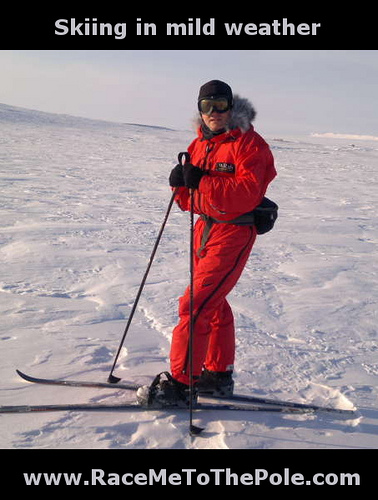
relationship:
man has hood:
[135, 76, 278, 411] [225, 96, 256, 131]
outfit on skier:
[153, 94, 277, 403] [136, 79, 278, 405]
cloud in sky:
[0, 45, 377, 115] [1, 50, 376, 135]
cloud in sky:
[0, 45, 377, 115] [157, 53, 189, 120]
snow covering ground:
[1, 103, 376, 448] [0, 105, 376, 451]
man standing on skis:
[137, 78, 278, 411] [94, 163, 225, 325]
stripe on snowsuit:
[181, 223, 253, 373] [169, 94, 277, 386]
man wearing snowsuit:
[135, 76, 278, 411] [169, 94, 277, 386]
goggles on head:
[197, 99, 232, 114] [161, 65, 280, 146]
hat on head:
[173, 62, 244, 107] [161, 65, 280, 146]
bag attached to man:
[242, 194, 282, 236] [135, 76, 278, 411]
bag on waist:
[242, 194, 282, 236] [184, 201, 261, 228]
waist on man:
[184, 201, 261, 228] [135, 76, 278, 411]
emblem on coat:
[210, 159, 244, 176] [170, 121, 277, 219]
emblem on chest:
[210, 159, 244, 176] [184, 140, 233, 189]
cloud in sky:
[0, 45, 377, 115] [325, 83, 360, 107]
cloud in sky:
[0, 45, 377, 115] [258, 57, 362, 129]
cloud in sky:
[0, 45, 377, 115] [5, 52, 321, 124]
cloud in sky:
[0, 45, 377, 115] [276, 74, 374, 108]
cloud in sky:
[13, 61, 305, 133] [1, 51, 369, 148]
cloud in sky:
[13, 61, 305, 133] [2, 44, 369, 140]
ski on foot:
[15, 362, 319, 409] [190, 367, 242, 395]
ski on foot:
[1, 396, 330, 426] [135, 372, 200, 409]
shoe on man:
[192, 364, 241, 407] [137, 78, 278, 411]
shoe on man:
[136, 369, 197, 406] [137, 78, 278, 411]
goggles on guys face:
[197, 99, 232, 114] [197, 89, 232, 132]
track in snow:
[237, 312, 307, 346] [1, 108, 375, 447]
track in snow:
[237, 272, 377, 397] [1, 108, 375, 447]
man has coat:
[135, 76, 278, 411] [168, 93, 279, 221]